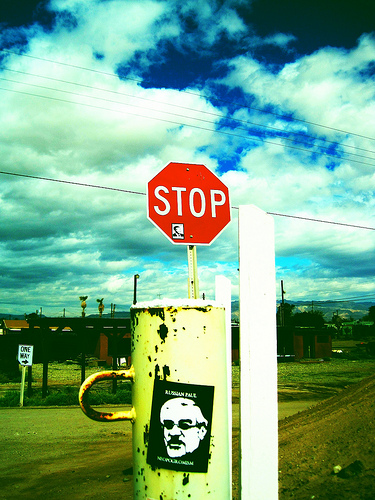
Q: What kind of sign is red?
A: Stop.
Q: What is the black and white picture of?
A: Mans head.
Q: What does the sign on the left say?
A: One way.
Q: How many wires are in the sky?
A: 5.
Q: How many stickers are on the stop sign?
A: 1.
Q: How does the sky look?
A: Cloudy.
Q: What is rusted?
A: The pole with the man's face.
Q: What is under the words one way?
A: Arrow.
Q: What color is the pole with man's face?
A: Yellow.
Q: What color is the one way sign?
A: Black and white.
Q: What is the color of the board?
A: Red and white.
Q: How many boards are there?
A: 1.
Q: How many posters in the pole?
A: 1.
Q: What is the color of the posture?
A: Black.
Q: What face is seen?
A: A man.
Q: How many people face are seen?
A: 1.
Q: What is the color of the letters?
A: White.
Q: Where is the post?
A: In Front of sign pole.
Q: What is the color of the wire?
A: Black.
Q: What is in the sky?
A: Puffy clouds.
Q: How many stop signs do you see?
A: One.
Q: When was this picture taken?
A: During the day.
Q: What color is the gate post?
A: Yellow.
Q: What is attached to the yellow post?
A: A picture of a man.